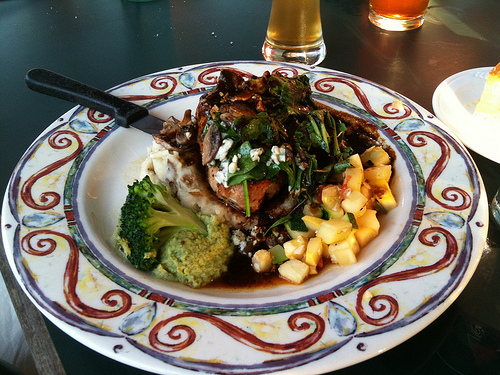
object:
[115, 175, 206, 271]
broccoli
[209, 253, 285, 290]
sauce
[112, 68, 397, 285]
mixture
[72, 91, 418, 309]
round plate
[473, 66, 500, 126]
corn bread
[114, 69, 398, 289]
meal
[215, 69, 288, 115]
meat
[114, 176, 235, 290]
veggies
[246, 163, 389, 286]
corn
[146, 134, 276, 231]
steak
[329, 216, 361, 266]
potato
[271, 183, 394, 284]
piece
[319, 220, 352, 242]
potatoe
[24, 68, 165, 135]
knife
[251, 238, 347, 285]
potatoe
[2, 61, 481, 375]
designs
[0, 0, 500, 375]
tabletop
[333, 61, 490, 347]
scrolls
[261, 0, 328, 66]
beer glass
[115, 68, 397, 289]
food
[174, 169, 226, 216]
potatoes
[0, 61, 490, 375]
plate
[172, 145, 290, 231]
feta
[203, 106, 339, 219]
mushrooms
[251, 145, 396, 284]
chopped food